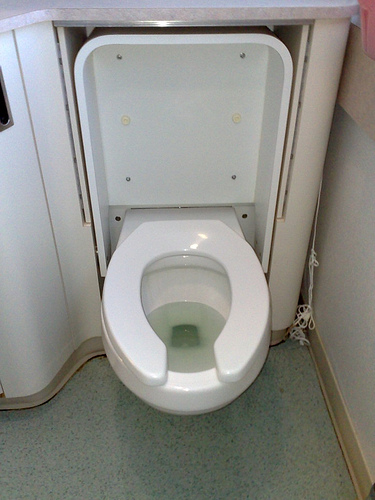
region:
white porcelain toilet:
[49, 177, 297, 407]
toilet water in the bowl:
[139, 285, 244, 384]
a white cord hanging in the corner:
[298, 182, 338, 372]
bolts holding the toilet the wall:
[114, 107, 146, 198]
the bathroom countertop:
[40, 1, 357, 44]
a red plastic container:
[345, 14, 373, 82]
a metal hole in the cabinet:
[0, 37, 21, 131]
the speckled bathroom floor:
[68, 431, 274, 496]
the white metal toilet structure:
[66, 23, 290, 233]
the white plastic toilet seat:
[90, 217, 317, 423]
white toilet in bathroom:
[98, 226, 284, 397]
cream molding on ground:
[294, 328, 370, 483]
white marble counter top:
[15, 6, 336, 33]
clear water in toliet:
[150, 294, 237, 369]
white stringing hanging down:
[285, 183, 326, 361]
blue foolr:
[38, 411, 212, 496]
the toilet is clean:
[94, 220, 289, 428]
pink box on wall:
[356, 6, 371, 46]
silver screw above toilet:
[110, 50, 128, 65]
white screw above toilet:
[122, 115, 131, 124]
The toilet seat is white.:
[84, 217, 266, 385]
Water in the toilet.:
[148, 298, 212, 369]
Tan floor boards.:
[294, 331, 366, 458]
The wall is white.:
[339, 159, 362, 383]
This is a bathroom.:
[7, 13, 371, 338]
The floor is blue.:
[76, 418, 290, 479]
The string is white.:
[281, 165, 319, 376]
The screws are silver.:
[106, 49, 129, 65]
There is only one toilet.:
[53, 12, 309, 428]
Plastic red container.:
[349, 0, 373, 56]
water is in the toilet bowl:
[94, 229, 327, 436]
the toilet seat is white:
[83, 210, 324, 398]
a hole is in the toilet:
[135, 280, 226, 372]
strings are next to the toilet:
[285, 160, 352, 355]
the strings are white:
[285, 226, 352, 391]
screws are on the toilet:
[90, 45, 289, 240]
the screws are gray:
[98, 45, 335, 275]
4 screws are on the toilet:
[94, 50, 319, 241]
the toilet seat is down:
[82, 214, 363, 457]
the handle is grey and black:
[0, 52, 33, 147]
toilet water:
[159, 321, 223, 371]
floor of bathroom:
[149, 449, 252, 490]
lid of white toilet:
[208, 311, 258, 389]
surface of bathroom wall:
[315, 365, 373, 435]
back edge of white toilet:
[159, 274, 202, 299]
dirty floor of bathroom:
[83, 411, 165, 453]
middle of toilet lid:
[202, 334, 222, 397]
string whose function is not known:
[289, 280, 305, 363]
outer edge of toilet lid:
[225, 324, 276, 358]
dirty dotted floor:
[67, 419, 143, 497]